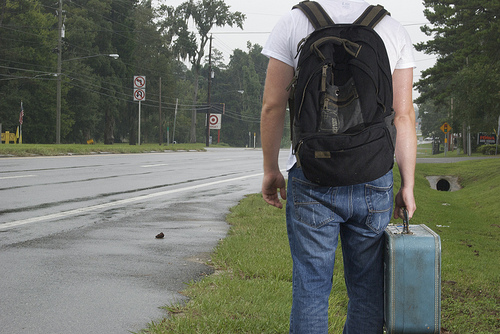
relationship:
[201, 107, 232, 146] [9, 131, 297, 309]
sign on road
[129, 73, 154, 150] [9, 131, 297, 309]
road signs near road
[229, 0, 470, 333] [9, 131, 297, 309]
person near road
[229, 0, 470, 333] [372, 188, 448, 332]
person holding case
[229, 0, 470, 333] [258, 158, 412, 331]
person in jeans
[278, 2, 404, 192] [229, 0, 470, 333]
backpack on person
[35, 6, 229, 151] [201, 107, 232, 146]
light above sign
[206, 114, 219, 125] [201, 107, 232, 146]
logo on sign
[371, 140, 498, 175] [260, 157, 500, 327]
driveway in grass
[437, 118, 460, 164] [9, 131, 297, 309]
yellow sign on road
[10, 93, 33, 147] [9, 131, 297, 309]
flag near road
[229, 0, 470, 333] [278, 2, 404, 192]
person with backpack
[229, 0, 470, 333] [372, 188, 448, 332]
person with case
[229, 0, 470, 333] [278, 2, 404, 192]
person with black backpack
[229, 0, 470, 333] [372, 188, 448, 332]
person with blue case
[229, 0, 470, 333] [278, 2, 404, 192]
person wearing backpack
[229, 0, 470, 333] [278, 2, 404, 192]
person wearing black backpack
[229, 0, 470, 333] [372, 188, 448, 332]
person holding blue case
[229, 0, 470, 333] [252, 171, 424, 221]
person has hands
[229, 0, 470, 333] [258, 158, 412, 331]
person wearing jeans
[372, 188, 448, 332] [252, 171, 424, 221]
case in hands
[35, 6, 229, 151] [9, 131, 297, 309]
light above road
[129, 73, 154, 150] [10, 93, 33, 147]
road signs near flag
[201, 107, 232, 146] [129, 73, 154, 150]
sign near road signs